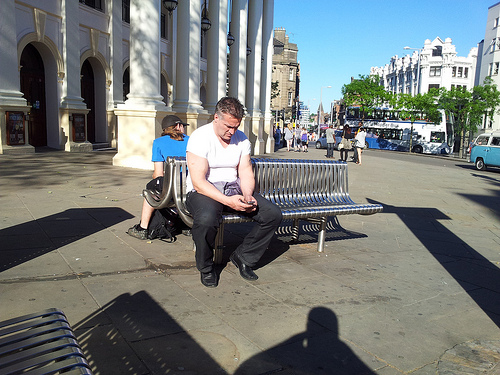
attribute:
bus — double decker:
[339, 98, 451, 153]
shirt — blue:
[183, 120, 251, 191]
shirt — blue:
[152, 130, 189, 160]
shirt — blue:
[354, 131, 367, 147]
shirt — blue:
[324, 127, 335, 143]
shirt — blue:
[301, 133, 306, 138]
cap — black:
[159, 112, 189, 126]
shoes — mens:
[194, 253, 256, 285]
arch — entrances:
[16, 37, 64, 76]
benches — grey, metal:
[284, 163, 353, 220]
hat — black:
[163, 113, 186, 128]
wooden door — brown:
[20, 49, 51, 152]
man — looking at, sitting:
[181, 96, 278, 287]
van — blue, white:
[337, 97, 452, 154]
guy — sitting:
[179, 99, 288, 289]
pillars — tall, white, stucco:
[117, 6, 282, 166]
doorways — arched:
[16, 37, 106, 149]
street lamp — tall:
[403, 45, 420, 152]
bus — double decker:
[342, 104, 453, 156]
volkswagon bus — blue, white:
[466, 129, 498, 166]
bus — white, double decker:
[306, 83, 453, 165]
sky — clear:
[271, 1, 491, 106]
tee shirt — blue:
[154, 132, 186, 163]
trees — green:
[337, 69, 499, 165]